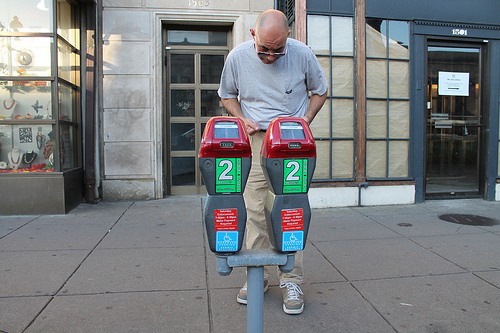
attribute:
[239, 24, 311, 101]
man — standing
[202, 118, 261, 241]
meter — red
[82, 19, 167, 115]
building — shiny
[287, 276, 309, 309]
shoes — white, black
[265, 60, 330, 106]
shirt — grey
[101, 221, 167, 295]
sidewalk — dirty